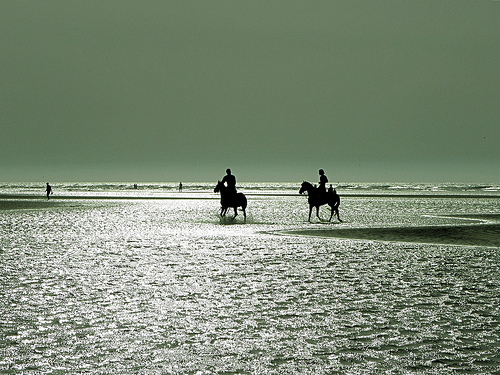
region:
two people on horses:
[203, 158, 387, 260]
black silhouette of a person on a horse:
[295, 168, 345, 228]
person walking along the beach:
[38, 181, 55, 201]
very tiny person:
[175, 183, 185, 195]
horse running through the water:
[207, 181, 254, 224]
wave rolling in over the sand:
[418, 202, 499, 240]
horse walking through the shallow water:
[293, 178, 345, 225]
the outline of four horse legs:
[305, 207, 343, 224]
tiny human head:
[315, 166, 327, 176]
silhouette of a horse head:
[296, 181, 311, 196]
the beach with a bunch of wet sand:
[3, 191, 490, 371]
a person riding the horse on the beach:
[214, 169, 249, 224]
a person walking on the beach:
[40, 182, 54, 197]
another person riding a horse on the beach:
[296, 162, 341, 222]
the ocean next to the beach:
[3, 181, 498, 197]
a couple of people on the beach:
[131, 179, 186, 191]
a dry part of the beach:
[306, 221, 496, 249]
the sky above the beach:
[3, 0, 499, 185]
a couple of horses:
[210, 181, 345, 216]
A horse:
[292, 161, 356, 245]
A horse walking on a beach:
[284, 147, 359, 258]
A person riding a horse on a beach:
[282, 153, 361, 239]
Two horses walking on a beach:
[178, 126, 366, 246]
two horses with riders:
[166, 145, 373, 236]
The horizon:
[350, 137, 498, 245]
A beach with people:
[32, 164, 404, 261]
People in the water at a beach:
[25, 161, 192, 219]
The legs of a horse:
[288, 201, 359, 245]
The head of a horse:
[284, 165, 313, 201]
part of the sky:
[308, 12, 393, 82]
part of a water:
[208, 279, 265, 346]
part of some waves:
[218, 227, 262, 268]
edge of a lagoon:
[406, 236, 436, 248]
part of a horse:
[228, 192, 252, 201]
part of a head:
[218, 157, 240, 180]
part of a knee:
[226, 202, 243, 216]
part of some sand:
[401, 222, 434, 252]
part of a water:
[236, 302, 280, 338]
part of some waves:
[199, 290, 259, 358]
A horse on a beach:
[292, 146, 366, 268]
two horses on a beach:
[183, 143, 373, 250]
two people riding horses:
[180, 132, 374, 248]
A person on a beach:
[27, 160, 67, 218]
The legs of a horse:
[304, 203, 352, 229]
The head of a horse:
[292, 171, 312, 196]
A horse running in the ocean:
[184, 144, 271, 260]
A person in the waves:
[163, 172, 198, 205]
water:
[113, 250, 324, 357]